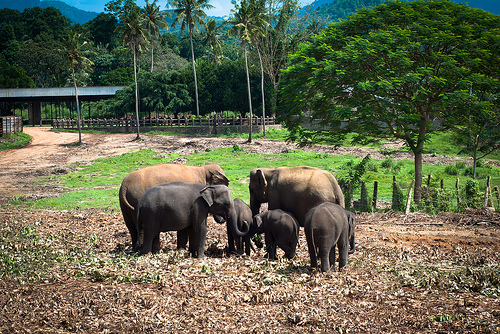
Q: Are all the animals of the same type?
A: Yes, all the animals are elephants.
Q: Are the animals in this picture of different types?
A: No, all the animals are elephants.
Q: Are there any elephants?
A: Yes, there is an elephant.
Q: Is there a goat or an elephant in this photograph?
A: Yes, there is an elephant.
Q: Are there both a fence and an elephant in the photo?
A: Yes, there are both an elephant and a fence.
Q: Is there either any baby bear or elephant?
A: Yes, there is a baby elephant.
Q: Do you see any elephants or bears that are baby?
A: Yes, the elephant is a baby.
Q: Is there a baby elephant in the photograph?
A: Yes, there is a baby elephant.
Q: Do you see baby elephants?
A: Yes, there is a baby elephant.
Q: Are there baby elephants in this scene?
A: Yes, there is a baby elephant.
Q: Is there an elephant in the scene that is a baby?
A: Yes, there is an elephant that is a baby.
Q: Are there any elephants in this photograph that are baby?
A: Yes, there is an elephant that is a baby.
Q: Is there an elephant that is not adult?
A: Yes, there is an baby elephant.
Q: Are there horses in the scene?
A: No, there are no horses.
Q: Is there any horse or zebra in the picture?
A: No, there are no horses or zebras.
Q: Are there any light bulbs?
A: No, there are no light bulbs.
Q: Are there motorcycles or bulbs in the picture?
A: No, there are no bulbs or motorcycles.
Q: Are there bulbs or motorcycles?
A: No, there are no bulbs or motorcycles.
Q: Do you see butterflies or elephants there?
A: Yes, there is an elephant.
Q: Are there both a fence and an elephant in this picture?
A: Yes, there are both an elephant and a fence.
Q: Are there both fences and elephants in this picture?
A: Yes, there are both an elephant and a fence.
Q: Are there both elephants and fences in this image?
A: Yes, there are both an elephant and a fence.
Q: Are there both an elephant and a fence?
A: Yes, there are both an elephant and a fence.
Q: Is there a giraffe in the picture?
A: No, there are no giraffes.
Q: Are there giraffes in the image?
A: No, there are no giraffes.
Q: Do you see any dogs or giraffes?
A: No, there are no giraffes or dogs.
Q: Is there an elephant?
A: Yes, there is an elephant.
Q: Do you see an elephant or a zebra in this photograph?
A: Yes, there is an elephant.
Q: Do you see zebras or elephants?
A: Yes, there is an elephant.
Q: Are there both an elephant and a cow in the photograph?
A: No, there is an elephant but no cows.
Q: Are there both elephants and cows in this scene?
A: No, there is an elephant but no cows.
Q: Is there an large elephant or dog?
A: Yes, there is a large elephant.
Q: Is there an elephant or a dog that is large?
A: Yes, the elephant is large.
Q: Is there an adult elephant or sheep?
A: Yes, there is an adult elephant.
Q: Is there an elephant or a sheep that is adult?
A: Yes, the elephant is adult.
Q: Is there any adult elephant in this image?
A: Yes, there is an adult elephant.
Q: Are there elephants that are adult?
A: Yes, there is an elephant that is adult.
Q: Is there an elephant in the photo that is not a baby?
A: Yes, there is a adult elephant.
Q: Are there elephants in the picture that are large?
A: Yes, there is a large elephant.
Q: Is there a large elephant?
A: Yes, there is a large elephant.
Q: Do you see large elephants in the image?
A: Yes, there is a large elephant.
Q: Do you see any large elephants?
A: Yes, there is a large elephant.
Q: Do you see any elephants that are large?
A: Yes, there is an elephant that is large.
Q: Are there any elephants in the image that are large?
A: Yes, there is an elephant that is large.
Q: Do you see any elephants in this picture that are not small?
A: Yes, there is a large elephant.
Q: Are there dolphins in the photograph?
A: No, there are no dolphins.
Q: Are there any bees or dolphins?
A: No, there are no dolphins or bees.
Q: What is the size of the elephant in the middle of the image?
A: The elephant is large.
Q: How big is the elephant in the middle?
A: The elephant is large.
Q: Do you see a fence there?
A: Yes, there is a fence.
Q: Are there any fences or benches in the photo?
A: Yes, there is a fence.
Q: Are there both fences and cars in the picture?
A: No, there is a fence but no cars.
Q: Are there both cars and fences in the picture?
A: No, there is a fence but no cars.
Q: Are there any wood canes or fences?
A: Yes, there is a wood fence.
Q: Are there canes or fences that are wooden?
A: Yes, the fence is wooden.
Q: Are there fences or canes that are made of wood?
A: Yes, the fence is made of wood.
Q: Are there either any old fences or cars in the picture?
A: Yes, there is an old fence.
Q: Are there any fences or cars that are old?
A: Yes, the fence is old.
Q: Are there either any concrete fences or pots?
A: Yes, there is a concrete fence.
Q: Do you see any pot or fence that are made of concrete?
A: Yes, the fence is made of concrete.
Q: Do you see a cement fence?
A: Yes, there is a fence that is made of cement.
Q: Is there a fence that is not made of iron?
A: Yes, there is a fence that is made of cement.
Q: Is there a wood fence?
A: Yes, there is a fence that is made of wood.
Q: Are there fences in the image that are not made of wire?
A: Yes, there is a fence that is made of wood.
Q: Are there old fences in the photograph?
A: Yes, there is an old fence.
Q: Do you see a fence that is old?
A: Yes, there is a fence that is old.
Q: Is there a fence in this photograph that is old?
A: Yes, there is a fence that is old.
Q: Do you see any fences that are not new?
A: Yes, there is a old fence.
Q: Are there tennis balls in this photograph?
A: No, there are no tennis balls.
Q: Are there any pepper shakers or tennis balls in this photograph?
A: No, there are no tennis balls or pepper shakers.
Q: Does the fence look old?
A: Yes, the fence is old.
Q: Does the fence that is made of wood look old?
A: Yes, the fence is old.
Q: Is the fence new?
A: No, the fence is old.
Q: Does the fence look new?
A: No, the fence is old.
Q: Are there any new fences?
A: No, there is a fence but it is old.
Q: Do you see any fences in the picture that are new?
A: No, there is a fence but it is old.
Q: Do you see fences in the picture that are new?
A: No, there is a fence but it is old.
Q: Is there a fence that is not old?
A: No, there is a fence but it is old.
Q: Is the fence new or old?
A: The fence is old.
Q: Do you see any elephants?
A: Yes, there is an elephant.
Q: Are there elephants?
A: Yes, there is an elephant.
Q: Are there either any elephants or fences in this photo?
A: Yes, there is an elephant.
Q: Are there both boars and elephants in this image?
A: No, there is an elephant but no boars.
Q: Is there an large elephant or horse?
A: Yes, there is a large elephant.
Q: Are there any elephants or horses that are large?
A: Yes, the elephant is large.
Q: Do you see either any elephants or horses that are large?
A: Yes, the elephant is large.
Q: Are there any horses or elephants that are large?
A: Yes, the elephant is large.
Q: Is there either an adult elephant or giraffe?
A: Yes, there is an adult elephant.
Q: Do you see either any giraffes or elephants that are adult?
A: Yes, the elephant is adult.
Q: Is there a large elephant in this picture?
A: Yes, there is a large elephant.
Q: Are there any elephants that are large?
A: Yes, there is a large elephant.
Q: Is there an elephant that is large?
A: Yes, there is an elephant that is large.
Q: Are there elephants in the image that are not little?
A: Yes, there is a large elephant.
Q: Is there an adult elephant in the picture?
A: Yes, there is an adult elephant.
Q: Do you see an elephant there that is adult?
A: Yes, there is an elephant that is adult.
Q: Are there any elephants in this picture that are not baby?
A: Yes, there is a adult elephant.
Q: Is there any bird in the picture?
A: No, there are no birds.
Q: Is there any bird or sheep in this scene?
A: No, there are no birds or sheep.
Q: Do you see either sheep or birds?
A: No, there are no birds or sheep.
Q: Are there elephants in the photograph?
A: Yes, there is an elephant.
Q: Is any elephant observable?
A: Yes, there is an elephant.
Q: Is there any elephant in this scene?
A: Yes, there is an elephant.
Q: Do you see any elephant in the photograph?
A: Yes, there is an elephant.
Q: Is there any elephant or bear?
A: Yes, there is an elephant.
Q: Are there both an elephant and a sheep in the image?
A: No, there is an elephant but no sheep.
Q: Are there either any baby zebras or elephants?
A: Yes, there is a baby elephant.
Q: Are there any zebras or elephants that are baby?
A: Yes, the elephant is a baby.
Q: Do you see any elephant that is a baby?
A: Yes, there is a baby elephant.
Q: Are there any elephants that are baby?
A: Yes, there is an elephant that is a baby.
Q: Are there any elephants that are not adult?
A: Yes, there is an baby elephant.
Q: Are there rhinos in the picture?
A: No, there are no rhinos.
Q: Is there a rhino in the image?
A: No, there are no rhinos.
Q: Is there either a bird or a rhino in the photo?
A: No, there are no rhinos or birds.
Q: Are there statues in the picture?
A: No, there are no statues.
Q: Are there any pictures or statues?
A: No, there are no statues or pictures.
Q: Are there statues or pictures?
A: No, there are no statues or pictures.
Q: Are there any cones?
A: No, there are no cones.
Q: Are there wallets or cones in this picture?
A: No, there are no cones or wallets.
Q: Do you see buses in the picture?
A: No, there are no buses.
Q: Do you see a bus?
A: No, there are no buses.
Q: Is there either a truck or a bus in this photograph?
A: No, there are no buses or trucks.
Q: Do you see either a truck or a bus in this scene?
A: No, there are no buses or trucks.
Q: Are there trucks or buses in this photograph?
A: No, there are no buses or trucks.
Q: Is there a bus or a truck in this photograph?
A: No, there are no buses or trucks.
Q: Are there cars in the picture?
A: No, there are no cars.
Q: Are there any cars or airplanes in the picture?
A: No, there are no cars or airplanes.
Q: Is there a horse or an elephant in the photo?
A: Yes, there is an elephant.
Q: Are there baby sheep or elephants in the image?
A: Yes, there is a baby elephant.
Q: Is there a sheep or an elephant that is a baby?
A: Yes, the elephant is a baby.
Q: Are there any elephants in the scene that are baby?
A: Yes, there is an elephant that is a baby.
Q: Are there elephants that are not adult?
A: Yes, there is an baby elephant.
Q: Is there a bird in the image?
A: No, there are no birds.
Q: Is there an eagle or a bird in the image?
A: No, there are no birds or eagles.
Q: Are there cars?
A: No, there are no cars.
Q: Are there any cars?
A: No, there are no cars.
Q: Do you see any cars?
A: No, there are no cars.